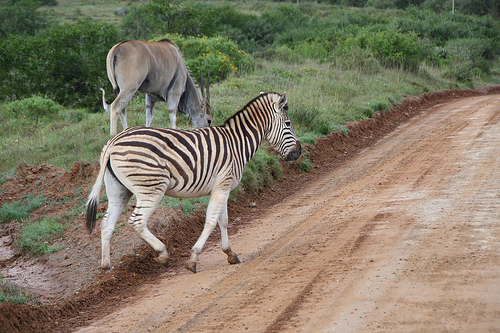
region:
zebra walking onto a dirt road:
[84, 105, 308, 287]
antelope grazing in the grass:
[91, 20, 250, 159]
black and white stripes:
[138, 127, 226, 205]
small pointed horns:
[190, 58, 239, 126]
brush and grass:
[243, 17, 465, 162]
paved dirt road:
[293, 77, 488, 311]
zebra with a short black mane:
[208, 75, 310, 200]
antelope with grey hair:
[113, 32, 208, 137]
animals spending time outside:
[39, 17, 434, 296]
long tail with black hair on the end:
[46, 127, 154, 254]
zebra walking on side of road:
[28, 97, 345, 302]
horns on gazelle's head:
[193, 77, 220, 111]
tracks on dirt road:
[235, 255, 330, 322]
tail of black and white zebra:
[73, 190, 105, 242]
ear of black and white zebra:
[268, 89, 290, 119]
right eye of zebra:
[275, 117, 292, 132]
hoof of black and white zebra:
[141, 241, 171, 266]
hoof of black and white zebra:
[179, 255, 207, 280]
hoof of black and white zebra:
[223, 249, 245, 268]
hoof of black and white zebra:
[96, 254, 122, 286]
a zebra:
[104, 107, 302, 269]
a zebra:
[147, 137, 262, 299]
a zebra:
[116, 99, 231, 205]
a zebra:
[84, 17, 289, 211]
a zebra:
[181, 95, 358, 314]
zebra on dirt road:
[56, 90, 340, 282]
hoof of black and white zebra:
[88, 250, 130, 275]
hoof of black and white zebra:
[187, 254, 212, 287]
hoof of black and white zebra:
[214, 240, 246, 267]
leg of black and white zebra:
[93, 220, 119, 274]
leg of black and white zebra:
[123, 219, 171, 269]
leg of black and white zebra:
[186, 223, 216, 276]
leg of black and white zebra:
[216, 223, 246, 280]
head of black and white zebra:
[245, 84, 314, 168]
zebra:
[68, 85, 340, 265]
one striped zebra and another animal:
[46, 35, 333, 286]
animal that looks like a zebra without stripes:
[70, 32, 227, 126]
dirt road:
[351, 52, 498, 222]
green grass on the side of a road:
[211, 17, 411, 87]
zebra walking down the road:
[83, 78, 301, 288]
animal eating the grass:
[66, 30, 242, 129]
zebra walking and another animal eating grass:
[42, 17, 428, 302]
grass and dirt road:
[350, 60, 487, 162]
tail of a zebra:
[71, 142, 106, 237]